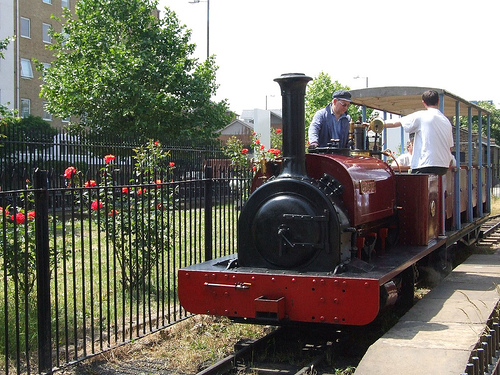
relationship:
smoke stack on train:
[253, 60, 328, 188] [172, 71, 499, 329]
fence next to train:
[0, 173, 240, 373] [172, 71, 499, 329]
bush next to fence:
[58, 130, 177, 294] [10, 182, 231, 362]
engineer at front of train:
[307, 89, 353, 152] [172, 71, 499, 329]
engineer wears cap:
[307, 89, 353, 152] [330, 87, 352, 100]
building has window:
[4, 1, 165, 135] [4, 1, 116, 124]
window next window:
[15, 8, 35, 44] [35, 15, 58, 47]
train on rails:
[172, 71, 499, 329] [202, 319, 371, 371]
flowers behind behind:
[57, 146, 189, 216] [1, 117, 262, 369]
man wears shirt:
[360, 90, 456, 175] [397, 103, 458, 175]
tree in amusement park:
[30, 3, 239, 213] [1, 0, 500, 375]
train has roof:
[172, 63, 499, 341] [333, 81, 498, 122]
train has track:
[172, 71, 499, 329] [201, 324, 365, 375]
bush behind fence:
[58, 138, 182, 293] [1, 117, 235, 371]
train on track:
[172, 63, 499, 341] [201, 324, 366, 373]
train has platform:
[172, 63, 499, 341] [350, 241, 499, 373]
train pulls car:
[172, 71, 499, 329] [339, 74, 497, 264]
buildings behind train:
[2, 8, 260, 208] [172, 63, 499, 341]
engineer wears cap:
[306, 84, 360, 158] [326, 90, 356, 108]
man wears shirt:
[370, 83, 468, 179] [397, 104, 464, 178]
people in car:
[444, 141, 494, 168] [350, 75, 499, 245]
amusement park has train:
[1, 17, 499, 372] [172, 63, 499, 341]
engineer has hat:
[307, 89, 353, 152] [327, 87, 355, 103]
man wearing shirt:
[360, 90, 456, 175] [396, 107, 456, 172]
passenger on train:
[381, 134, 421, 182] [172, 63, 499, 341]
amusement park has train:
[1, 0, 500, 375] [172, 63, 499, 341]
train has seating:
[172, 63, 499, 341] [438, 153, 498, 220]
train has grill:
[172, 63, 499, 341] [162, 262, 385, 332]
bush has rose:
[58, 138, 182, 293] [59, 161, 83, 181]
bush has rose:
[58, 138, 182, 293] [85, 199, 106, 214]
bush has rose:
[58, 138, 182, 293] [108, 206, 120, 216]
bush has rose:
[58, 138, 182, 293] [98, 151, 114, 166]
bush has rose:
[58, 138, 182, 293] [116, 186, 133, 198]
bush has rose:
[58, 138, 182, 293] [132, 182, 152, 202]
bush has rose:
[58, 138, 182, 293] [84, 178, 99, 187]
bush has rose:
[58, 138, 182, 293] [150, 136, 165, 147]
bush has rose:
[58, 138, 182, 293] [162, 161, 174, 168]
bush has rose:
[58, 138, 182, 293] [148, 201, 164, 213]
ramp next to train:
[342, 247, 495, 373] [172, 63, 499, 341]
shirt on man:
[391, 101, 461, 179] [350, 80, 459, 183]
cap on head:
[325, 87, 360, 107] [321, 87, 358, 119]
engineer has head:
[307, 89, 353, 152] [321, 87, 358, 119]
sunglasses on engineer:
[331, 98, 354, 109] [307, 89, 353, 152]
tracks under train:
[167, 216, 498, 374] [172, 63, 499, 341]